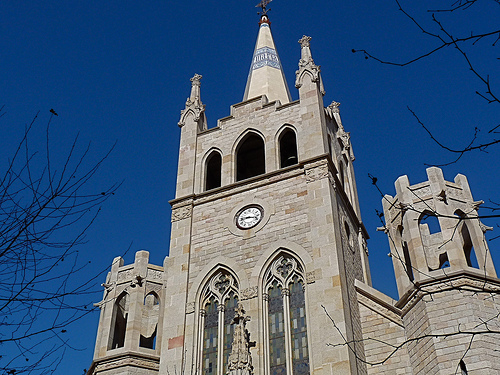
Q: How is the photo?
A: Clear.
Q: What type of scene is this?
A: Outdoor.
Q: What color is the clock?
A: White.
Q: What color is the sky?
A: Blue.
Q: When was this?
A: Daytime.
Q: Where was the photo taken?
A: Outside a church.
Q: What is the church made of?
A: Bricks.